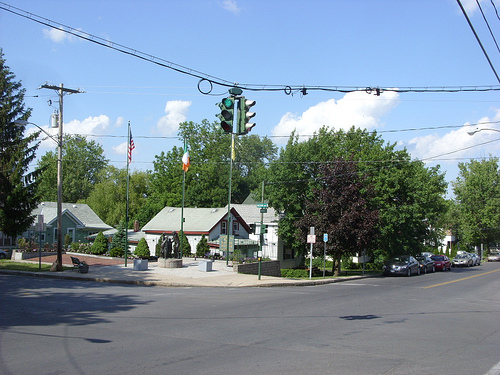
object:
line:
[419, 268, 499, 289]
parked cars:
[380, 253, 420, 277]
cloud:
[270, 86, 400, 149]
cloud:
[20, 114, 114, 163]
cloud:
[35, 24, 112, 55]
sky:
[0, 0, 498, 200]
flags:
[126, 124, 136, 166]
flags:
[179, 137, 191, 173]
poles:
[180, 172, 186, 232]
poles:
[122, 120, 130, 268]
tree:
[0, 47, 52, 245]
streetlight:
[218, 94, 260, 137]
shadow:
[0, 262, 161, 343]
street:
[1, 260, 498, 372]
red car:
[431, 252, 453, 272]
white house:
[140, 205, 254, 259]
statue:
[163, 236, 174, 258]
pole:
[54, 82, 65, 272]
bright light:
[238, 99, 257, 135]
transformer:
[49, 111, 57, 131]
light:
[222, 96, 233, 107]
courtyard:
[0, 251, 344, 286]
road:
[0, 259, 498, 374]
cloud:
[153, 97, 189, 140]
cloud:
[405, 108, 497, 202]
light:
[10, 118, 62, 147]